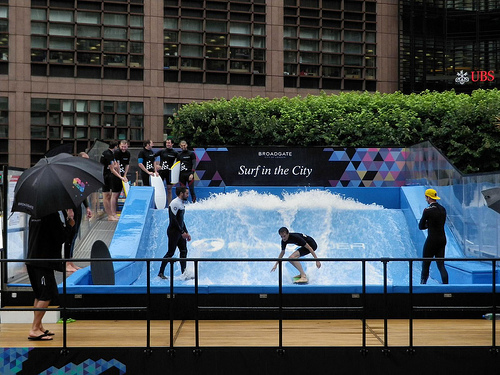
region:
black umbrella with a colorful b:
[12, 143, 119, 254]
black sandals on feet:
[0, 323, 56, 359]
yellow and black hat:
[400, 181, 443, 213]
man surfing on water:
[202, 212, 322, 329]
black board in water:
[42, 226, 119, 327]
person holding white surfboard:
[127, 134, 167, 210]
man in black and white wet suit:
[102, 185, 209, 295]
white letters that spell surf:
[227, 155, 261, 185]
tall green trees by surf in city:
[119, 95, 491, 175]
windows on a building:
[20, 99, 141, 149]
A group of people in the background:
[91, 130, 211, 206]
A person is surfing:
[250, 201, 335, 284]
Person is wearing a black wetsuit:
[267, 222, 325, 258]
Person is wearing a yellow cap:
[420, 183, 446, 208]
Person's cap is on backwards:
[418, 180, 452, 212]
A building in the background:
[1, 0, 499, 165]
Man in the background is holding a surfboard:
[136, 136, 172, 206]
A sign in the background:
[195, 145, 410, 185]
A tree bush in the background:
[163, 88, 498, 175]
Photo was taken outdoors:
[2, 3, 498, 370]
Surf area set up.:
[59, 180, 499, 294]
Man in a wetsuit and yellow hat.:
[417, 186, 452, 288]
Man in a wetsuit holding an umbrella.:
[11, 150, 106, 340]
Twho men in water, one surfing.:
[62, 177, 499, 289]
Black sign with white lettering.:
[206, 142, 334, 185]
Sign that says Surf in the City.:
[205, 147, 333, 189]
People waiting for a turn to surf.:
[100, 135, 200, 206]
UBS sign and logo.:
[452, 68, 498, 87]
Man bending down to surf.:
[269, 223, 324, 286]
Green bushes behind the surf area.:
[174, 88, 499, 176]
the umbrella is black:
[11, 135, 97, 215]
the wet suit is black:
[405, 204, 460, 287]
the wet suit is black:
[161, 195, 194, 267]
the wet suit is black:
[106, 148, 208, 192]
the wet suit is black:
[277, 223, 323, 270]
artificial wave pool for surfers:
[120, 176, 461, 290]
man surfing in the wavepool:
[268, 223, 324, 292]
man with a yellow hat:
[409, 182, 459, 289]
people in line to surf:
[98, 126, 200, 221]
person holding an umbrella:
[18, 193, 84, 345]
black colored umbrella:
[13, 150, 109, 228]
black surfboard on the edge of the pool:
[86, 235, 120, 290]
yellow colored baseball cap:
[422, 186, 442, 203]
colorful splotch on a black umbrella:
[67, 173, 92, 200]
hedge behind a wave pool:
[162, 81, 498, 177]